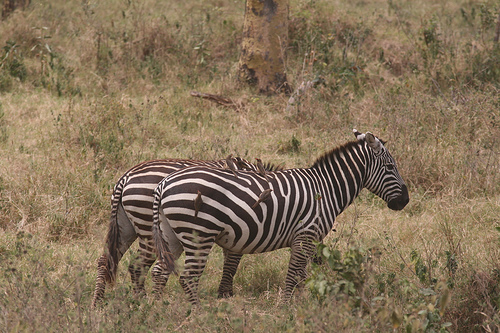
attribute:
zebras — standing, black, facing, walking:
[110, 117, 435, 294]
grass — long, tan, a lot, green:
[313, 238, 393, 307]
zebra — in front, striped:
[154, 143, 429, 291]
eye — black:
[378, 151, 406, 179]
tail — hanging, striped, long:
[132, 194, 191, 270]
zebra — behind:
[89, 157, 230, 286]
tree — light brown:
[235, 2, 317, 88]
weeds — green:
[318, 247, 377, 302]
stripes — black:
[217, 196, 270, 250]